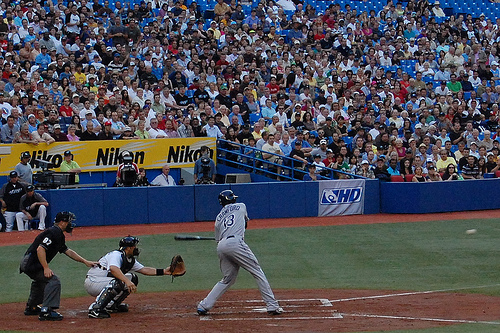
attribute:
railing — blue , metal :
[217, 139, 367, 182]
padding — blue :
[43, 177, 497, 217]